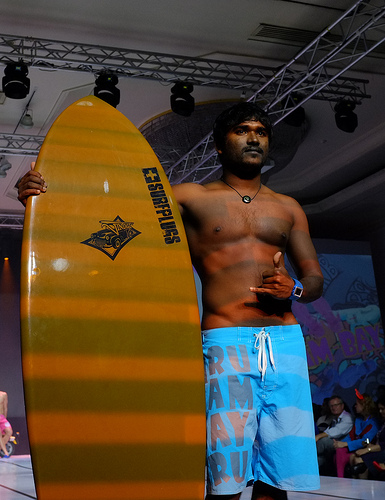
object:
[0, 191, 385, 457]
wall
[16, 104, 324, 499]
man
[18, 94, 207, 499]
surfboard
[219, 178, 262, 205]
necklace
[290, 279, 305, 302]
watch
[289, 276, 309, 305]
wrist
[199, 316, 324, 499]
shorts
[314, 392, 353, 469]
man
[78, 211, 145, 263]
logo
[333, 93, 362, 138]
light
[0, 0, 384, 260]
ceiling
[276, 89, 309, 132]
light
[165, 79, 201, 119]
light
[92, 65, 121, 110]
light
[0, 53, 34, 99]
light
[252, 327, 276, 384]
string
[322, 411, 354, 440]
shirt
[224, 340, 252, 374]
letter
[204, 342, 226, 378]
letter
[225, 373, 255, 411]
letter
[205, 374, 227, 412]
letter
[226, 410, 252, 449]
letter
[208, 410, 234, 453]
letter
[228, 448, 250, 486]
letter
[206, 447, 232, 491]
letter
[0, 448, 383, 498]
stage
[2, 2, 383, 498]
picture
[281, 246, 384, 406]
graffiti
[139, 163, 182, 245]
writing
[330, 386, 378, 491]
audience